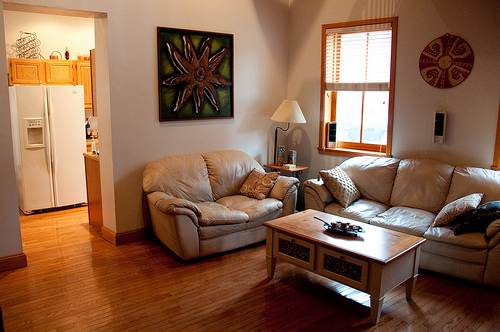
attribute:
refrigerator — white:
[8, 83, 90, 215]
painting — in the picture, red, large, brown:
[157, 26, 234, 121]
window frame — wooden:
[319, 17, 399, 157]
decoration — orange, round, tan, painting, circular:
[418, 33, 477, 91]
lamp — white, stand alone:
[268, 95, 311, 167]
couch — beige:
[141, 150, 499, 288]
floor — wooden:
[1, 202, 499, 331]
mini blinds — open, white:
[323, 21, 396, 91]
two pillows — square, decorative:
[430, 188, 500, 235]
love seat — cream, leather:
[144, 148, 301, 260]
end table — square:
[262, 159, 310, 178]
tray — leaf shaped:
[312, 216, 366, 238]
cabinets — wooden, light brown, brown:
[9, 46, 115, 230]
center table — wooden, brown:
[260, 205, 428, 326]